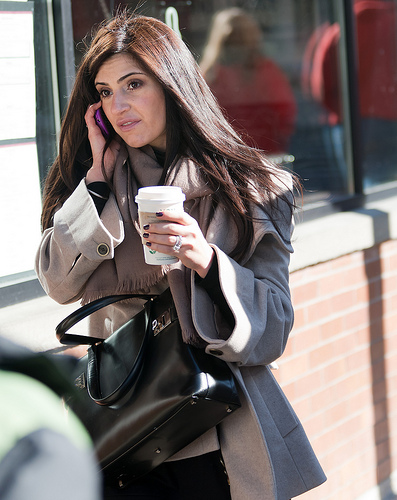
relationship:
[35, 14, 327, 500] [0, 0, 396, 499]
woman in front of building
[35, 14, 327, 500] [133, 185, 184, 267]
woman has coffee cup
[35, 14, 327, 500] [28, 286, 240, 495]
woman has handbag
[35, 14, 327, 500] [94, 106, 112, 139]
woman talking on cell phone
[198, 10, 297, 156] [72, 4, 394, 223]
reflection in window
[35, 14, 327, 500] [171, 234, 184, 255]
woman has ring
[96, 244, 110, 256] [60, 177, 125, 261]
button on coat cuff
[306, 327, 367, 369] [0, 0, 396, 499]
bricks are on side of building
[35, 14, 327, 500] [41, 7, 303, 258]
woman has hair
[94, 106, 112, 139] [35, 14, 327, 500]
cell phone next to woman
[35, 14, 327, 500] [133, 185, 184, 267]
woman holding coffee cup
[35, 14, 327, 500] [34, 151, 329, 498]
woman has coat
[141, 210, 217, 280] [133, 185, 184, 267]
hand holding coffee cup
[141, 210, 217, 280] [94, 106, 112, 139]
hand holding cell phone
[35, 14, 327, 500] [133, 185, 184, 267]
woman carrying coffee cup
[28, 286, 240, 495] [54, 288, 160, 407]
handbag has handle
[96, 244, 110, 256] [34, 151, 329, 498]
button on coat